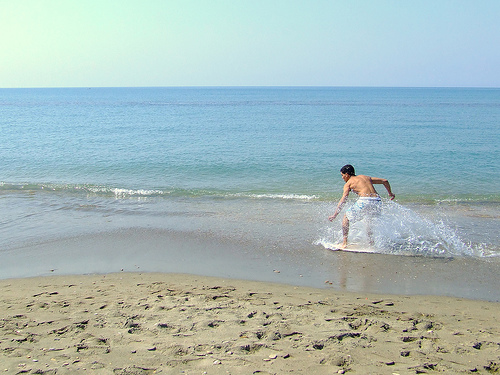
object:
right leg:
[366, 216, 381, 250]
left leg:
[339, 209, 360, 250]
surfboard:
[332, 241, 405, 256]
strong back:
[350, 174, 379, 197]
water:
[268, 190, 499, 264]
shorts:
[343, 194, 384, 224]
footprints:
[397, 332, 423, 344]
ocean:
[0, 87, 500, 190]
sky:
[0, 0, 500, 91]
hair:
[339, 164, 357, 177]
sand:
[32, 314, 92, 349]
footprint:
[51, 323, 70, 335]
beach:
[0, 272, 498, 375]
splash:
[315, 197, 498, 261]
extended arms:
[332, 187, 351, 218]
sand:
[31, 203, 292, 279]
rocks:
[260, 356, 274, 364]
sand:
[339, 251, 499, 292]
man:
[327, 163, 398, 251]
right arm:
[371, 176, 392, 196]